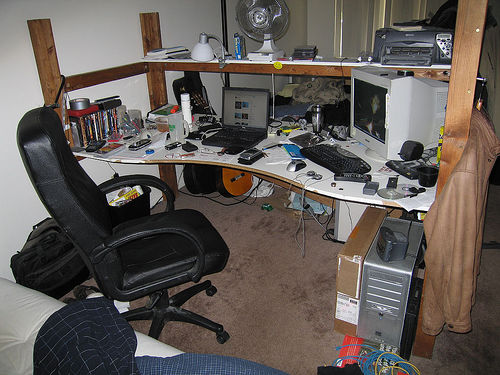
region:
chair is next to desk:
[15, 108, 230, 346]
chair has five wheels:
[16, 104, 231, 345]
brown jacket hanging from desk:
[423, 108, 498, 341]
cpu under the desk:
[358, 211, 425, 356]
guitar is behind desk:
[179, 75, 257, 197]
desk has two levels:
[73, 31, 453, 348]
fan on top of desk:
[236, 0, 288, 64]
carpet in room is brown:
[48, 177, 498, 370]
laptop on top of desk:
[200, 80, 268, 150]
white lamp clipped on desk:
[186, 31, 229, 73]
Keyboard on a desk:
[300, 139, 373, 177]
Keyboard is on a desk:
[298, 140, 371, 180]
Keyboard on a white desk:
[301, 140, 370, 177]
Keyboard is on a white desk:
[296, 141, 371, 178]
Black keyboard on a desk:
[299, 140, 374, 179]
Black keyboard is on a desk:
[296, 140, 373, 178]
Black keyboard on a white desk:
[295, 142, 375, 179]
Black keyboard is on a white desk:
[295, 137, 373, 179]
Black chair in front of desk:
[10, 105, 251, 347]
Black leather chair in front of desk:
[15, 103, 238, 347]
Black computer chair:
[10, 103, 235, 351]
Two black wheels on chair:
[204, 274, 229, 351]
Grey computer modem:
[360, 201, 420, 361]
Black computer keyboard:
[298, 133, 371, 178]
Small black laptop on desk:
[205, 72, 270, 164]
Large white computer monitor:
[342, 61, 450, 171]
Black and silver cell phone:
[237, 145, 262, 167]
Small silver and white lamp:
[193, 24, 230, 71]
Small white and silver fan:
[235, 2, 298, 62]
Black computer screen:
[352, 74, 387, 146]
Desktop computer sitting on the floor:
[357, 214, 426, 363]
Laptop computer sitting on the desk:
[209, 85, 271, 148]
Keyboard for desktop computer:
[297, 142, 372, 178]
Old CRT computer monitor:
[349, 62, 454, 164]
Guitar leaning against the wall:
[185, 63, 255, 200]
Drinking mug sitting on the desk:
[167, 113, 189, 145]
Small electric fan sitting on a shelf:
[232, 0, 293, 61]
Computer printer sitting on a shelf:
[371, 20, 452, 69]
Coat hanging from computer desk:
[420, 111, 498, 336]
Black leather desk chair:
[14, 104, 230, 347]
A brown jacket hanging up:
[419, 109, 499, 334]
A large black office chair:
[16, 106, 233, 339]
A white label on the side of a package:
[335, 293, 359, 323]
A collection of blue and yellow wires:
[332, 346, 417, 373]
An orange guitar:
[184, 86, 254, 196]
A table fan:
[233, 0, 290, 63]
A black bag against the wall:
[9, 222, 96, 297]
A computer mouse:
[287, 159, 305, 172]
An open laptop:
[202, 87, 273, 146]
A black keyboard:
[307, 140, 366, 179]